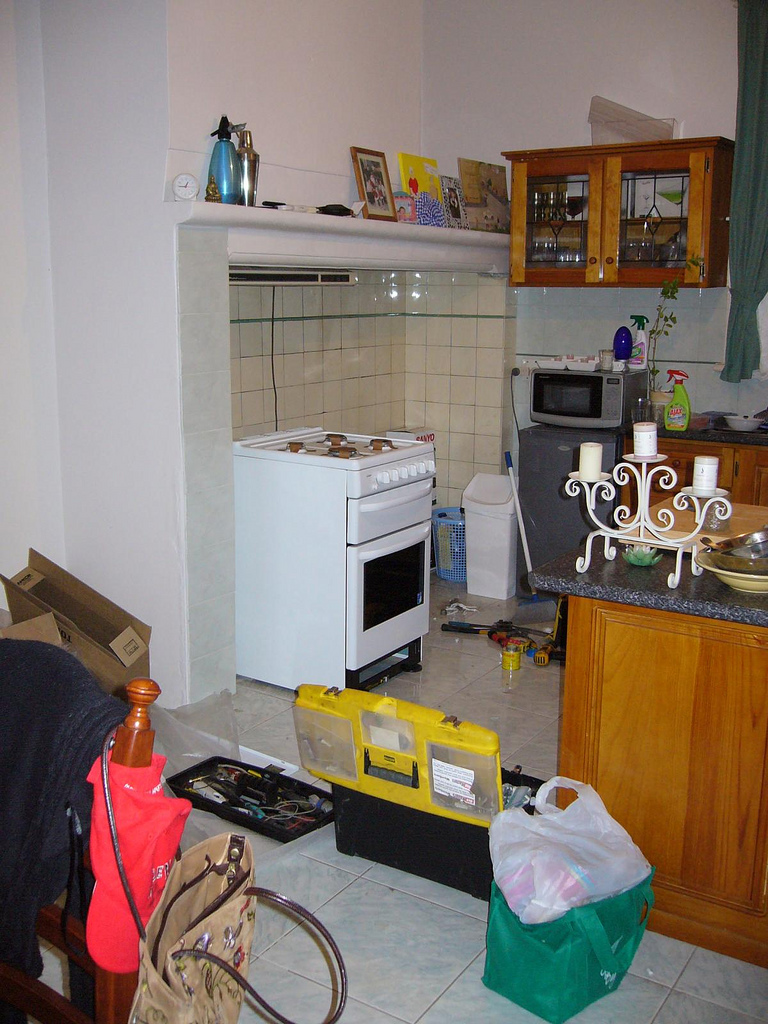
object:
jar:
[502, 644, 520, 671]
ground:
[464, 670, 544, 697]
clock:
[173, 170, 200, 202]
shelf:
[164, 162, 390, 253]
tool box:
[302, 684, 552, 912]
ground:
[282, 851, 478, 927]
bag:
[479, 773, 656, 1017]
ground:
[477, 963, 730, 1007]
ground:
[367, 873, 430, 961]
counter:
[691, 406, 761, 445]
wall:
[65, 228, 135, 400]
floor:
[319, 862, 393, 949]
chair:
[0, 641, 155, 1021]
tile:
[306, 325, 372, 364]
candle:
[578, 443, 600, 482]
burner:
[287, 441, 304, 454]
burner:
[326, 446, 357, 459]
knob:
[406, 460, 423, 477]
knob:
[427, 462, 436, 470]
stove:
[235, 429, 433, 706]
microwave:
[528, 361, 649, 433]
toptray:
[160, 744, 343, 843]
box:
[0, 545, 152, 704]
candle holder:
[564, 421, 735, 590]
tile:
[59, 277, 142, 365]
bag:
[130, 829, 353, 1019]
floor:
[129, 706, 758, 1018]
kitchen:
[1, 2, 755, 906]